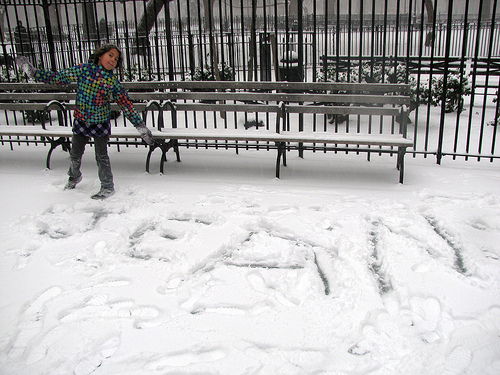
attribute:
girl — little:
[17, 44, 151, 198]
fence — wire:
[3, 0, 499, 158]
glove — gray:
[138, 125, 155, 146]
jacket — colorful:
[34, 63, 150, 127]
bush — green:
[194, 64, 232, 112]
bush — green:
[435, 73, 468, 109]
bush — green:
[365, 60, 386, 87]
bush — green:
[323, 74, 355, 123]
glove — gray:
[18, 53, 35, 79]